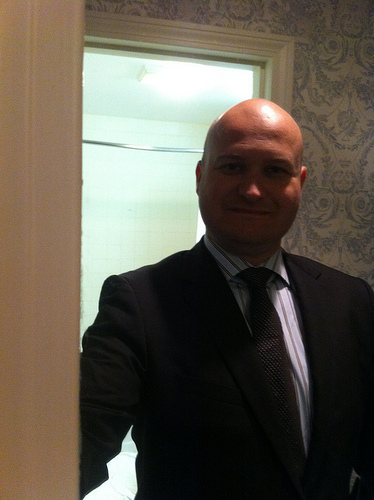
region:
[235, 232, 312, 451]
Striped shirt under jacket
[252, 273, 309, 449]
Dark colored tie around his neck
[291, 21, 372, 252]
Light purple floral wallpaper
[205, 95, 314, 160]
The man has a bald head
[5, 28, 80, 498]
The door is white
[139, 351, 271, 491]
Black colored jacket on the man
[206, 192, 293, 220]
The man is smiling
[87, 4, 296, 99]
White door trim around the door behind the man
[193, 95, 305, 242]
Facial features of the man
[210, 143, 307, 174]
Very nice shapely eyebrows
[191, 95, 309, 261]
shiny hairless head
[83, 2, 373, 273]
white and gray design on wallpaper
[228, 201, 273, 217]
thin lipped smiley mouth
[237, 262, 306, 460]
dark patterned tie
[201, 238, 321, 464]
grey and white button down shirt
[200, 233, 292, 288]
grey striped collar of shirt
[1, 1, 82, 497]
white painted doorway frame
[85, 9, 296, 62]
white top frame of window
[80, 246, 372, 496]
black fitted suit jacket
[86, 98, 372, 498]
happy bald man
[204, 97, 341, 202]
the man is bald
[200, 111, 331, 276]
the man is smiling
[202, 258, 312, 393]
the neck tie is on the neck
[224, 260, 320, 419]
the shirt is stripes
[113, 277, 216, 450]
the coat is black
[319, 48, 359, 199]
the wallpaper is flower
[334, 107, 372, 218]
the wallpaper is white and gray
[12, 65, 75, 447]
the door is open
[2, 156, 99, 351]
the door is white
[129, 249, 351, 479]
the man is wearing a suit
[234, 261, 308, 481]
Black and white spotted tie the man is wearing.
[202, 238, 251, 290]
The left collar of the man's shirt.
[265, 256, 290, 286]
The right collar of the man's striped shirt.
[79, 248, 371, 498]
The black suit jacket the man is wearing.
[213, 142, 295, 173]
The bald man's two eyebrows.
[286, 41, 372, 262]
The printed wallpaper to the right of the man.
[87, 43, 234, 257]
The window behind the man.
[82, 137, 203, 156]
The metal rod across the window.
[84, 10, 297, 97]
The window frame around the window.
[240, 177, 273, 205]
The nose of the man in the black suit jacket.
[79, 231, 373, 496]
the man is wearing a black jacket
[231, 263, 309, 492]
the man is wearing a brown tie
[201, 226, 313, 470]
the man is wearing a white shirt with stripes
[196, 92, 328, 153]
the man's head is bald and shiny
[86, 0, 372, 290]
the wall behind the man has a classic blue wallpaper on it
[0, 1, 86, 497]
the door is white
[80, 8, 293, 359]
the door jamb is white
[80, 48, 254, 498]
the room behind the man is very bright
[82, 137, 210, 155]
a metal shower curtain in the room behind the man